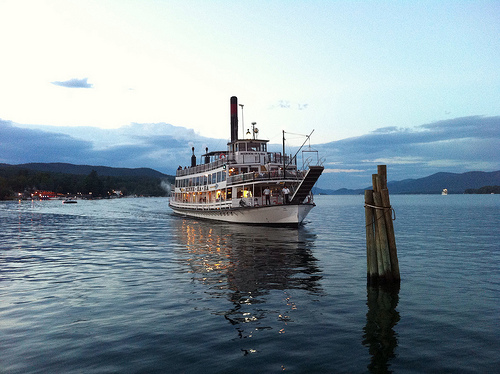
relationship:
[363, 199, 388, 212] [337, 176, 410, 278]
string around post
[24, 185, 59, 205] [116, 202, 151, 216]
houses on shore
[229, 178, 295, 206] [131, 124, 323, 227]
people on boat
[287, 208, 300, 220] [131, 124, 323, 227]
light attached to boat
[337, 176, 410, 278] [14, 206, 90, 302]
post on top of waters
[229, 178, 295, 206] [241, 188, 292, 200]
people wearing shirts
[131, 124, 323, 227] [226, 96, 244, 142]
boat has stack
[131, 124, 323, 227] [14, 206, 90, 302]
boat on waters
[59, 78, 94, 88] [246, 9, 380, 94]
clouds in sky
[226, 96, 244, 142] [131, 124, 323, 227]
stack on top of boat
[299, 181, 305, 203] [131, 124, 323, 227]
stairs on boat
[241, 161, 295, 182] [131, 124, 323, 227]
crew on boat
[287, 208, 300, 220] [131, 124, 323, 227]
light on boat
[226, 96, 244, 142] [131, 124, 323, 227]
stack on boat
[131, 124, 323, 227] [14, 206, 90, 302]
boat on top of waters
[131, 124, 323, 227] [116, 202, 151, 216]
boat along shore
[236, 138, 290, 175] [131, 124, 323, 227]
cabin on boat